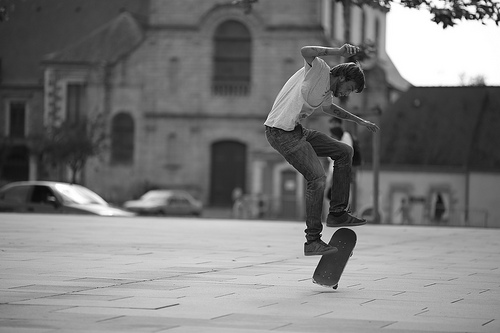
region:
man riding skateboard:
[203, 9, 448, 331]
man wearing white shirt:
[231, 33, 353, 133]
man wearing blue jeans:
[268, 111, 357, 224]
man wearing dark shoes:
[290, 186, 371, 263]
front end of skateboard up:
[299, 198, 366, 299]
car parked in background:
[5, 152, 148, 254]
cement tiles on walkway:
[0, 216, 492, 328]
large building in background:
[0, 0, 476, 220]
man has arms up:
[291, 32, 388, 143]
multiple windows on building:
[0, 3, 494, 256]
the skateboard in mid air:
[312, 226, 355, 289]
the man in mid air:
[264, 43, 379, 258]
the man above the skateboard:
[264, 43, 378, 258]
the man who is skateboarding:
[262, 42, 379, 257]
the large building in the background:
[0, 0, 498, 226]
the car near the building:
[123, 188, 202, 218]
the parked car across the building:
[0, 180, 132, 216]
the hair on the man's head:
[331, 60, 364, 92]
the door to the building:
[209, 138, 247, 205]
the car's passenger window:
[30, 185, 56, 204]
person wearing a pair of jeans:
[245, 24, 392, 292]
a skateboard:
[298, 214, 378, 303]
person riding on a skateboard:
[255, 28, 392, 301]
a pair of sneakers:
[287, 193, 377, 266]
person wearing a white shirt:
[251, 11, 383, 318]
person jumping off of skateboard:
[212, 13, 409, 299]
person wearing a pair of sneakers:
[235, 19, 412, 294]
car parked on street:
[117, 171, 237, 227]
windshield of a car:
[44, 169, 114, 208]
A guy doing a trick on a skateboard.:
[257, 39, 384, 295]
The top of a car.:
[3, 180, 132, 217]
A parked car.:
[123, 188, 205, 218]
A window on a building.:
[206, 18, 256, 96]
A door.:
[270, 160, 302, 218]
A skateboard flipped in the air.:
[311, 225, 357, 293]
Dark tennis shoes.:
[300, 210, 364, 255]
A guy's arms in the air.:
[300, 40, 382, 138]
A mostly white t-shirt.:
[265, 58, 338, 132]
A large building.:
[2, 1, 494, 226]